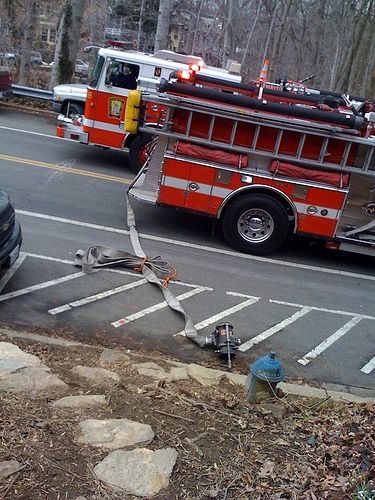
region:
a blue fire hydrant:
[239, 348, 288, 402]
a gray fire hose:
[69, 141, 213, 349]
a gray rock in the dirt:
[89, 444, 183, 497]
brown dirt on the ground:
[0, 331, 373, 498]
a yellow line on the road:
[0, 148, 140, 189]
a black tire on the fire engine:
[212, 194, 299, 256]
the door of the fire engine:
[88, 57, 147, 152]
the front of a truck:
[48, 72, 94, 122]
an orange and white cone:
[255, 57, 275, 85]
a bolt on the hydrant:
[267, 347, 278, 360]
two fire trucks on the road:
[61, 32, 366, 237]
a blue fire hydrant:
[233, 342, 315, 433]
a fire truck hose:
[108, 134, 248, 361]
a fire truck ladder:
[143, 86, 351, 187]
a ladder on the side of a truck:
[119, 83, 369, 175]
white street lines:
[75, 208, 361, 402]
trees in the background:
[132, 4, 359, 83]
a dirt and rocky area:
[27, 343, 259, 498]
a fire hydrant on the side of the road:
[209, 334, 337, 439]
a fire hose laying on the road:
[69, 160, 247, 376]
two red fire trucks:
[37, 38, 366, 314]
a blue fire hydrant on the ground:
[247, 340, 297, 416]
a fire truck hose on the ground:
[88, 203, 239, 348]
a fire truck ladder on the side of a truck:
[132, 73, 369, 184]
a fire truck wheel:
[195, 153, 324, 267]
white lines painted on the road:
[49, 211, 369, 372]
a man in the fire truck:
[92, 55, 140, 96]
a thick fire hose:
[112, 195, 230, 353]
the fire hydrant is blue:
[249, 351, 291, 408]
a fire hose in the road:
[140, 150, 207, 386]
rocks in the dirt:
[13, 347, 178, 498]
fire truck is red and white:
[109, 55, 233, 212]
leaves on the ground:
[291, 421, 369, 492]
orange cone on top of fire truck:
[250, 52, 280, 97]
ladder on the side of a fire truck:
[187, 95, 372, 182]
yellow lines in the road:
[13, 136, 130, 193]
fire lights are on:
[181, 50, 208, 96]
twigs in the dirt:
[158, 387, 304, 498]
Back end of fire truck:
[145, 68, 348, 263]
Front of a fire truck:
[60, 56, 156, 170]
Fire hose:
[102, 176, 251, 384]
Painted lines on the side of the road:
[21, 254, 138, 341]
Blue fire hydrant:
[239, 342, 286, 410]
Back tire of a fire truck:
[219, 186, 294, 265]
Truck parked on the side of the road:
[31, 68, 95, 130]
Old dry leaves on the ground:
[205, 404, 365, 493]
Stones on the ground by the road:
[6, 349, 189, 494]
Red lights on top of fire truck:
[171, 57, 211, 95]